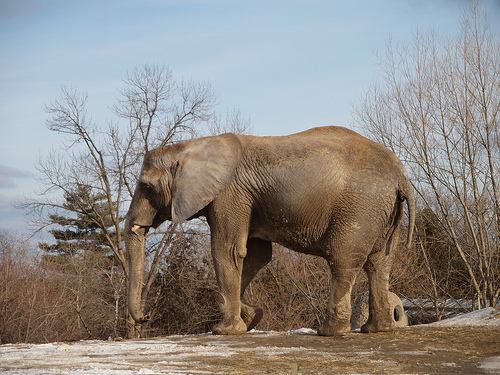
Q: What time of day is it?
A: Daytime.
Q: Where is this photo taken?
A: On a field.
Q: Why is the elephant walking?
A: It is looking for food.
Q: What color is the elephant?
A: Gray.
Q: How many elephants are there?
A: One.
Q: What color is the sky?
A: Blue.